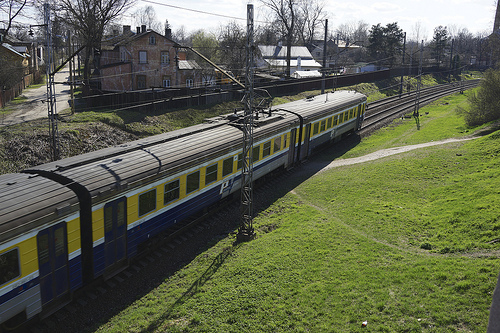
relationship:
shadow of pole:
[128, 243, 241, 328] [321, 18, 329, 97]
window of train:
[136, 187, 158, 218] [1, 82, 355, 331]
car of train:
[282, 79, 370, 157] [1, 82, 355, 331]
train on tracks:
[1, 90, 368, 331] [361, 75, 484, 145]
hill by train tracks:
[47, 87, 499, 331] [357, 77, 484, 133]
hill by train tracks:
[2, 70, 499, 175] [357, 77, 484, 133]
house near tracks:
[54, 8, 277, 126] [364, 73, 484, 151]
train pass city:
[1, 82, 355, 331] [5, 6, 395, 117]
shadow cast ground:
[143, 247, 244, 331] [141, 240, 244, 330]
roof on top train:
[113, 132, 193, 174] [267, 79, 370, 172]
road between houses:
[3, 50, 77, 125] [1, 19, 222, 99]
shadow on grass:
[136, 241, 242, 333] [193, 184, 493, 329]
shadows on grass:
[408, 118, 425, 133] [193, 184, 493, 329]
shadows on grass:
[52, 107, 142, 137] [193, 184, 493, 329]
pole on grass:
[220, 13, 273, 245] [378, 173, 452, 240]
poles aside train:
[194, 27, 329, 287] [65, 100, 340, 287]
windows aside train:
[134, 130, 289, 219] [1, 82, 355, 331]